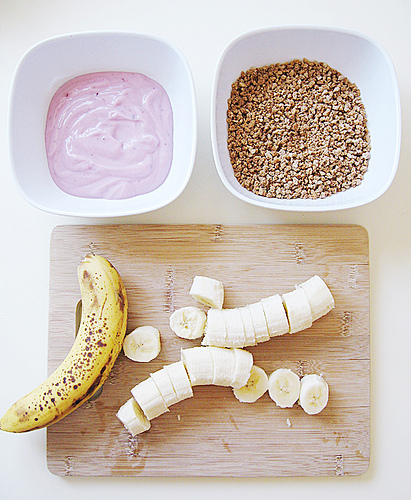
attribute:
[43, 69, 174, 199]
yogurt — pink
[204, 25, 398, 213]
bowl — white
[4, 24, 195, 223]
bowl — white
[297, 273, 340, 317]
slice — yellow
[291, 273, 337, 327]
banana — yellow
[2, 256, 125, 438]
spots — brown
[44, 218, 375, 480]
cutting board — wooden, brown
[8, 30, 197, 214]
bowl — white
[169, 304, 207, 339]
slice — yellow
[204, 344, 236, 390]
slice — yellow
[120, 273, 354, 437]
banana — yellow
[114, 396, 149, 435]
slice — yellow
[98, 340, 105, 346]
spot — dark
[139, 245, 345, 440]
banana slices — sliced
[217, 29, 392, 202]
bowl — white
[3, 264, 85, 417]
banana peel — black, bruising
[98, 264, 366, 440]
bananas — sliced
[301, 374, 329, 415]
banana slice — yellow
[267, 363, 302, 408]
banana slice — yellow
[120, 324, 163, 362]
banana slice — yellow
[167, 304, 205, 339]
banana slice — yellow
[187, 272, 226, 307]
banana slice — yellow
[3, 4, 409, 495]
counter — white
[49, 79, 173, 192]
yogurt — in a dish, pink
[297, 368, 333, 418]
slice — yellow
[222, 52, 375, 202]
nuts — brown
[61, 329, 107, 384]
spots — brown